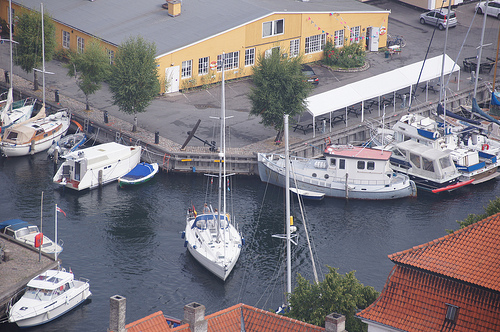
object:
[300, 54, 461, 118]
tent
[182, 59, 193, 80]
window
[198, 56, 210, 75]
window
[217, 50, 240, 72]
window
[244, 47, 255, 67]
window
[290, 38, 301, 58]
window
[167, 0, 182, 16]
chimney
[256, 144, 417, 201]
boat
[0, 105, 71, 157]
boat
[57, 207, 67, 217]
flag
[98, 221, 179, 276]
water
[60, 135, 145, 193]
white boat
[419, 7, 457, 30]
suv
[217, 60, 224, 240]
mast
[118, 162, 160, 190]
boat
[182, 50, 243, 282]
boat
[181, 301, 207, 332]
gray chimney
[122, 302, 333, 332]
roof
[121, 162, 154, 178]
cover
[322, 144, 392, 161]
roof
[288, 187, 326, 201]
boat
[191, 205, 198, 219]
person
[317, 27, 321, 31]
flags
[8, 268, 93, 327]
boat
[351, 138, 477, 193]
boat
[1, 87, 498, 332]
marina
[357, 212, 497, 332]
roof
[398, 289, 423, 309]
tiles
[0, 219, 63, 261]
boat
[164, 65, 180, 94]
door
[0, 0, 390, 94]
building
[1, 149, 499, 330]
sea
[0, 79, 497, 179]
pier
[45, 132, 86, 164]
boat